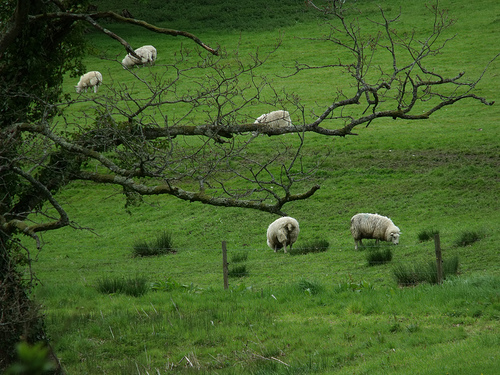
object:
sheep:
[345, 210, 403, 253]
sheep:
[261, 214, 304, 255]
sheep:
[116, 43, 160, 72]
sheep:
[72, 73, 106, 98]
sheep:
[252, 105, 293, 139]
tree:
[0, 3, 95, 374]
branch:
[0, 104, 338, 168]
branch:
[0, 2, 500, 239]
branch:
[6, 165, 100, 259]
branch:
[72, 159, 286, 217]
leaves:
[129, 139, 151, 149]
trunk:
[0, 1, 25, 374]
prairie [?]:
[1, 0, 499, 374]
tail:
[284, 219, 295, 233]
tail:
[348, 216, 358, 226]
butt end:
[278, 217, 300, 238]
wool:
[265, 217, 303, 243]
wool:
[348, 210, 391, 244]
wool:
[260, 108, 291, 130]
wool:
[135, 44, 157, 57]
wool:
[80, 69, 101, 84]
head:
[387, 226, 402, 241]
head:
[264, 241, 280, 254]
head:
[73, 84, 86, 96]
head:
[120, 58, 132, 69]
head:
[249, 127, 260, 139]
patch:
[131, 226, 176, 252]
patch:
[220, 247, 251, 257]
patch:
[364, 248, 393, 263]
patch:
[287, 237, 331, 256]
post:
[219, 237, 232, 291]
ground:
[14, 0, 500, 372]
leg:
[281, 242, 288, 255]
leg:
[350, 234, 359, 252]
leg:
[92, 84, 98, 95]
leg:
[141, 61, 147, 69]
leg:
[359, 235, 365, 248]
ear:
[387, 230, 397, 238]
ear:
[398, 228, 403, 234]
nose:
[393, 241, 400, 248]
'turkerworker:
[149, 53, 155, 60]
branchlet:
[315, 13, 463, 126]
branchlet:
[230, 157, 294, 196]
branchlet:
[145, 163, 178, 193]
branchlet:
[60, 218, 105, 237]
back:
[350, 210, 392, 228]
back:
[259, 215, 296, 236]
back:
[251, 105, 292, 118]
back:
[117, 48, 151, 54]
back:
[72, 70, 102, 78]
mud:
[367, 141, 500, 170]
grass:
[232, 343, 286, 374]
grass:
[128, 230, 171, 251]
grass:
[220, 258, 250, 274]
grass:
[291, 233, 327, 255]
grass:
[455, 228, 477, 244]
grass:
[396, 252, 454, 285]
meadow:
[1, 1, 497, 374]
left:
[3, 11, 248, 373]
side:
[265, 222, 287, 247]